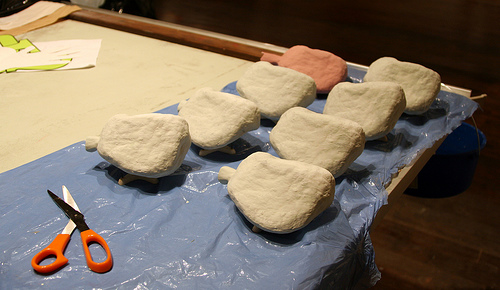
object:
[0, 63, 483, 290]
cloth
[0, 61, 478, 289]
plastic bag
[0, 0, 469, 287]
table top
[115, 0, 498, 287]
floor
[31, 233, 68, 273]
handles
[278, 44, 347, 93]
rock